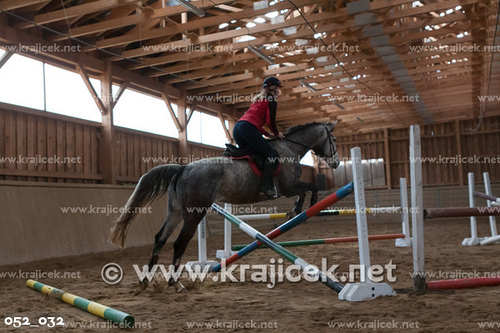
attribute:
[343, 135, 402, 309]
pole — green , yellow 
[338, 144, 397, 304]
white pole — with a base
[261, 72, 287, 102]
helmet — black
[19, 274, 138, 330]
pole — yellow, green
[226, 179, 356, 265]
pole — red, blue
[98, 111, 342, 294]
horse — dappled, grey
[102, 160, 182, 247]
tail — grey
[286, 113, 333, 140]
mane — black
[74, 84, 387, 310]
horse — gray 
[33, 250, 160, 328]
pole — yellow, green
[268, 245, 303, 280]
pole — green, white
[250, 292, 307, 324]
dirt — brown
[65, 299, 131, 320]
pole — green and yellow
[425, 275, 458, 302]
pole — red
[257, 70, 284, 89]
hat — black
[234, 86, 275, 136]
shirt — red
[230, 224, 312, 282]
pole — green and white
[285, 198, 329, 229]
post — blue and red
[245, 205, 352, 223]
pole — white, green and yellow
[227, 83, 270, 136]
shirt — red and blue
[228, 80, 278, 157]
lady — red and blue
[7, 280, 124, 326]
pole — yellow and green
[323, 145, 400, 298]
frame — white